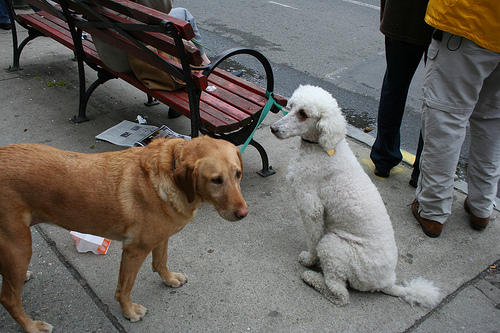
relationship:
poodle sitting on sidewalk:
[269, 84, 440, 309] [0, 0, 499, 330]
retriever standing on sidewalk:
[0, 135, 249, 332] [0, 0, 499, 330]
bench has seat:
[0, 0, 288, 179] [18, 9, 287, 129]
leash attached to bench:
[240, 89, 289, 153] [0, 0, 288, 179]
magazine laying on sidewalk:
[95, 118, 193, 146] [0, 0, 499, 330]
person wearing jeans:
[368, 0, 434, 188] [368, 36, 431, 178]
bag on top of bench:
[125, 37, 209, 91] [0, 0, 288, 179]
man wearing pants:
[411, 0, 499, 237] [415, 27, 500, 224]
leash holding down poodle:
[240, 89, 289, 153] [269, 84, 440, 309]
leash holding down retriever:
[240, 89, 289, 153] [0, 135, 249, 332]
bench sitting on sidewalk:
[0, 0, 288, 179] [0, 0, 499, 330]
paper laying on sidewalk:
[70, 230, 112, 255] [0, 0, 499, 330]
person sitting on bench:
[87, 0, 211, 74] [0, 0, 288, 179]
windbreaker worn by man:
[425, 0, 498, 54] [411, 0, 499, 237]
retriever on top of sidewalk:
[0, 135, 249, 332] [0, 0, 499, 330]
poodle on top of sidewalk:
[269, 84, 440, 309] [0, 0, 499, 330]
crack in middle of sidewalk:
[33, 223, 126, 332] [0, 0, 499, 330]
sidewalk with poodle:
[0, 0, 499, 330] [269, 84, 440, 309]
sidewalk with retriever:
[0, 0, 499, 330] [0, 135, 249, 332]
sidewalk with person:
[0, 0, 499, 330] [368, 0, 434, 188]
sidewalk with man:
[0, 0, 499, 330] [411, 0, 499, 237]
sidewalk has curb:
[0, 0, 499, 330] [343, 118, 499, 210]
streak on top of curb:
[365, 150, 416, 179] [343, 118, 499, 210]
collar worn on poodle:
[299, 137, 336, 157] [269, 84, 440, 309]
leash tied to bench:
[240, 89, 289, 153] [0, 0, 288, 179]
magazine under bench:
[95, 118, 193, 146] [0, 0, 288, 179]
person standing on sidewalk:
[368, 0, 434, 188] [0, 0, 499, 330]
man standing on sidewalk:
[411, 0, 499, 237] [0, 0, 499, 330]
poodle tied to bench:
[269, 84, 440, 309] [0, 0, 288, 179]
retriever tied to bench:
[0, 135, 249, 332] [0, 0, 288, 179]